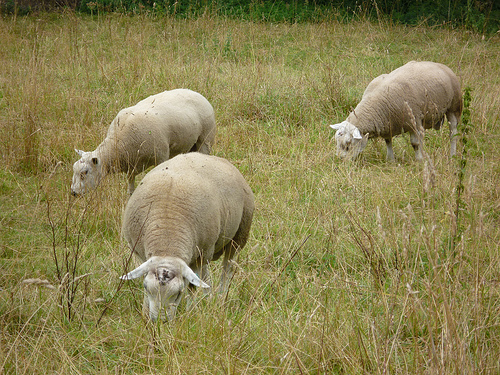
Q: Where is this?
A: This is at the field.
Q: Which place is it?
A: It is a field.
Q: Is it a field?
A: Yes, it is a field.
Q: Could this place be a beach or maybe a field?
A: It is a field.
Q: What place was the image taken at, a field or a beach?
A: It was taken at a field.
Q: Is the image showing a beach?
A: No, the picture is showing a field.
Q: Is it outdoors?
A: Yes, it is outdoors.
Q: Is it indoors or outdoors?
A: It is outdoors.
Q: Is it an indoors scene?
A: No, it is outdoors.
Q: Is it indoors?
A: No, it is outdoors.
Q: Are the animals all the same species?
A: Yes, all the animals are sheep.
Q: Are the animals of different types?
A: No, all the animals are sheep.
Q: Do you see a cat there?
A: No, there are no cats.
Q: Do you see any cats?
A: No, there are no cats.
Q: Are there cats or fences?
A: No, there are no cats or fences.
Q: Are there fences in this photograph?
A: No, there are no fences.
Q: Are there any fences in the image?
A: No, there are no fences.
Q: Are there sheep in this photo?
A: Yes, there is a sheep.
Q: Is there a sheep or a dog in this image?
A: Yes, there is a sheep.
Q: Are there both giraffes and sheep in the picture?
A: No, there is a sheep but no giraffes.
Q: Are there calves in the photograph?
A: No, there are no calves.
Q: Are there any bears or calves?
A: No, there are no calves or bears.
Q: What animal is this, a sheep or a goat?
A: This is a sheep.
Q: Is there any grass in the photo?
A: Yes, there is grass.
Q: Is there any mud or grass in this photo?
A: Yes, there is grass.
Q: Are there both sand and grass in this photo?
A: No, there is grass but no sand.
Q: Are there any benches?
A: No, there are no benches.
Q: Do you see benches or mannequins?
A: No, there are no benches or mannequins.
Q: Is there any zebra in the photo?
A: No, there are no zebras.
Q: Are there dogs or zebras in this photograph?
A: No, there are no zebras or dogs.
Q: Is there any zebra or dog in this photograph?
A: No, there are no zebras or dogs.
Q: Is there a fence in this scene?
A: No, there are no fences.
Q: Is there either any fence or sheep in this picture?
A: Yes, there is a sheep.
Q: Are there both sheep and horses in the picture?
A: No, there is a sheep but no horses.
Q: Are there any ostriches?
A: No, there are no ostriches.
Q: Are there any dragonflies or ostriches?
A: No, there are no ostriches or dragonflies.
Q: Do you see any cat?
A: No, there are no cats.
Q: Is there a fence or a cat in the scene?
A: No, there are no cats or fences.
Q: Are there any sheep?
A: Yes, there is a sheep.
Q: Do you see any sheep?
A: Yes, there is a sheep.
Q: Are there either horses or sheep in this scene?
A: Yes, there is a sheep.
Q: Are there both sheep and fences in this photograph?
A: No, there is a sheep but no fences.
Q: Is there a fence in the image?
A: No, there are no fences.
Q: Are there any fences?
A: No, there are no fences.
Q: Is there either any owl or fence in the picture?
A: No, there are no fences or owls.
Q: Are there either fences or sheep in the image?
A: Yes, there is a sheep.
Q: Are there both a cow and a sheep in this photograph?
A: No, there is a sheep but no cows.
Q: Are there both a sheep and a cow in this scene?
A: No, there is a sheep but no cows.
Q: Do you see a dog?
A: No, there are no dogs.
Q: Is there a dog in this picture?
A: No, there are no dogs.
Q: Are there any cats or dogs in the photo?
A: No, there are no dogs or cats.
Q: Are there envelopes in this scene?
A: No, there are no envelopes.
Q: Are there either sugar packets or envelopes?
A: No, there are no envelopes or sugar packets.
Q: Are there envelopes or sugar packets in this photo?
A: No, there are no envelopes or sugar packets.